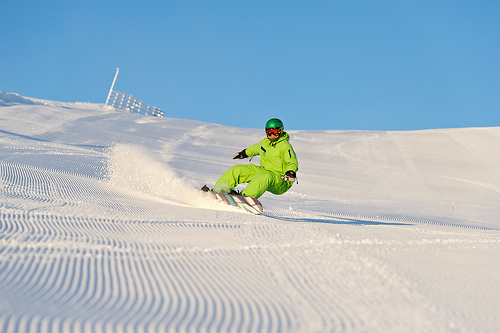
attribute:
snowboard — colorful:
[199, 183, 265, 217]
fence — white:
[100, 83, 178, 123]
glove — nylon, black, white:
[227, 147, 254, 170]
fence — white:
[106, 90, 166, 125]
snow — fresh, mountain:
[0, 93, 499, 331]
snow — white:
[3, 90, 214, 332]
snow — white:
[295, 122, 497, 332]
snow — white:
[4, 206, 499, 329]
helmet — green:
[253, 105, 295, 142]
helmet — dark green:
[264, 117, 287, 133]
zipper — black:
[278, 145, 298, 162]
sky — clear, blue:
[1, 0, 496, 125]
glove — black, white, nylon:
[278, 167, 302, 185]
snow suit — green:
[218, 141, 297, 200]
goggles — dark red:
[262, 126, 284, 138]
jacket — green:
[238, 133, 301, 178]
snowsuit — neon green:
[213, 135, 302, 196]